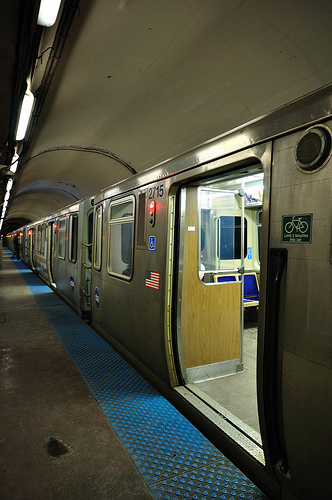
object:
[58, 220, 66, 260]
window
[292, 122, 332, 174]
speaker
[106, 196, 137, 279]
passenger window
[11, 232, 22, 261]
man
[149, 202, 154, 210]
light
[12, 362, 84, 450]
ground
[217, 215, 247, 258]
window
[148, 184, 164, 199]
number 2715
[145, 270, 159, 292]
flag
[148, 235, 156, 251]
sign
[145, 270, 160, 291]
bench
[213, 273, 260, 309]
seat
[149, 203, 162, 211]
red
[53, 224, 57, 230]
red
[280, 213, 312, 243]
sign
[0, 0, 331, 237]
ceiling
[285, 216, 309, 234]
bicycle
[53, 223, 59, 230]
light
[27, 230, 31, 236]
light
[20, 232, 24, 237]
light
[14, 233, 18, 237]
light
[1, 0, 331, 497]
subway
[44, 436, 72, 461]
puddle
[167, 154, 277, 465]
entrance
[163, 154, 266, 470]
door